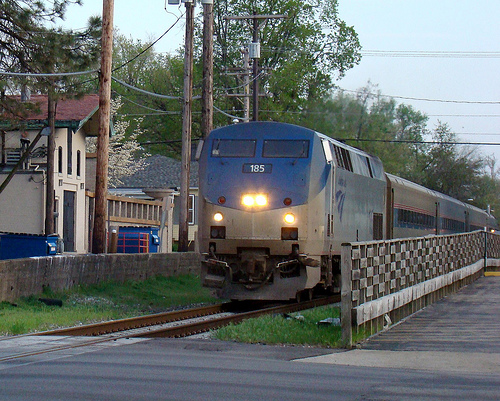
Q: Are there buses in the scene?
A: No, there are no buses.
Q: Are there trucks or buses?
A: No, there are no buses or trucks.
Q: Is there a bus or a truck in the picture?
A: No, there are no buses or trucks.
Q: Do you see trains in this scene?
A: Yes, there is a train.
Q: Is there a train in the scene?
A: Yes, there is a train.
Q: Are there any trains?
A: Yes, there is a train.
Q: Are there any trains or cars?
A: Yes, there is a train.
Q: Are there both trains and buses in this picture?
A: No, there is a train but no buses.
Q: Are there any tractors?
A: No, there are no tractors.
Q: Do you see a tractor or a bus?
A: No, there are no tractors or buses.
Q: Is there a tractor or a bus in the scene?
A: No, there are no tractors or buses.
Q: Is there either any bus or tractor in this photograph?
A: No, there are no tractors or buses.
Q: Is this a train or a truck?
A: This is a train.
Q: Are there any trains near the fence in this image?
A: Yes, there is a train near the fence.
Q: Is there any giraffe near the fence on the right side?
A: No, there is a train near the fence.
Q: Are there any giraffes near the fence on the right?
A: No, there is a train near the fence.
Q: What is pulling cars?
A: The train is pulling cars.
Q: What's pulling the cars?
A: The train is pulling cars.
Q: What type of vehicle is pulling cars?
A: The vehicle is a train.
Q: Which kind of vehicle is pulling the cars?
A: The vehicle is a train.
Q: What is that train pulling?
A: The train is pulling cars.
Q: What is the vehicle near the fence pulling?
A: The train is pulling cars.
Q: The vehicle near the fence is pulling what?
A: The train is pulling cars.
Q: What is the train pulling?
A: The train is pulling cars.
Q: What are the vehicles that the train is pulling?
A: The vehicles are cars.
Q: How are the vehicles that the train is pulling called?
A: The vehicles are cars.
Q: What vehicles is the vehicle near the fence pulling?
A: The train is pulling cars.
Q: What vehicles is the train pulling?
A: The train is pulling cars.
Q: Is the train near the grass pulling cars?
A: Yes, the train is pulling cars.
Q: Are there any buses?
A: No, there are no buses.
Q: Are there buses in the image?
A: No, there are no buses.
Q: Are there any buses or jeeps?
A: No, there are no buses or jeeps.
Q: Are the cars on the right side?
A: Yes, the cars are on the right of the image.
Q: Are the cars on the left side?
A: No, the cars are on the right of the image.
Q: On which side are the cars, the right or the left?
A: The cars are on the right of the image.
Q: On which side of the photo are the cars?
A: The cars are on the right of the image.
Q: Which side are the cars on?
A: The cars are on the right of the image.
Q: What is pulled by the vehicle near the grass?
A: The cars are pulled by the train.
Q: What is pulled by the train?
A: The cars are pulled by the train.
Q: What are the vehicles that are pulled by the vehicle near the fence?
A: The vehicles are cars.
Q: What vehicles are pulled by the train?
A: The vehicles are cars.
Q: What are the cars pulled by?
A: The cars are pulled by the train.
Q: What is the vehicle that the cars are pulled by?
A: The vehicle is a train.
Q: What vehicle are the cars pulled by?
A: The cars are pulled by the train.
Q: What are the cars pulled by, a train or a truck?
A: The cars are pulled by a train.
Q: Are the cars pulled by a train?
A: Yes, the cars are pulled by a train.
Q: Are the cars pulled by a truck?
A: No, the cars are pulled by a train.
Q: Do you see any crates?
A: No, there are no crates.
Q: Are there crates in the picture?
A: No, there are no crates.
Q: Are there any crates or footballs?
A: No, there are no crates or footballs.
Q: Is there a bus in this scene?
A: No, there are no buses.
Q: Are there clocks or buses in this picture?
A: No, there are no buses or clocks.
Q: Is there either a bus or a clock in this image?
A: No, there are no buses or clocks.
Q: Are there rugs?
A: No, there are no rugs.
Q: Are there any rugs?
A: No, there are no rugs.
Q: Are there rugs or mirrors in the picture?
A: No, there are no rugs or mirrors.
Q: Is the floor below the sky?
A: Yes, the floor is below the sky.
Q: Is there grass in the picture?
A: Yes, there is grass.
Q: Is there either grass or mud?
A: Yes, there is grass.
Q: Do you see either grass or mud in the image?
A: Yes, there is grass.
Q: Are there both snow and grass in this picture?
A: No, there is grass but no snow.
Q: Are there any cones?
A: No, there are no cones.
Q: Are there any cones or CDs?
A: No, there are no cones or cds.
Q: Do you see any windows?
A: Yes, there is a window.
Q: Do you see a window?
A: Yes, there is a window.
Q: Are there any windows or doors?
A: Yes, there is a window.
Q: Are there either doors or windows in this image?
A: Yes, there is a window.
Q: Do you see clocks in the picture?
A: No, there are no clocks.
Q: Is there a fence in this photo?
A: Yes, there is a fence.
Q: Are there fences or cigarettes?
A: Yes, there is a fence.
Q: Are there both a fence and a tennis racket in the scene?
A: No, there is a fence but no rackets.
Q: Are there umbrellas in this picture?
A: No, there are no umbrellas.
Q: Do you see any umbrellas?
A: No, there are no umbrellas.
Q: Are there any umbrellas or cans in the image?
A: No, there are no umbrellas or cans.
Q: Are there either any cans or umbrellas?
A: No, there are no umbrellas or cans.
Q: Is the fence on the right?
A: Yes, the fence is on the right of the image.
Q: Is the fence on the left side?
A: No, the fence is on the right of the image.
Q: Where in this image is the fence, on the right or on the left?
A: The fence is on the right of the image.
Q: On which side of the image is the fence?
A: The fence is on the right of the image.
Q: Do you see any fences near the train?
A: Yes, there is a fence near the train.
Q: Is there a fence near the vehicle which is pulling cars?
A: Yes, there is a fence near the train.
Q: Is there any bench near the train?
A: No, there is a fence near the train.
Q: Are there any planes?
A: No, there are no planes.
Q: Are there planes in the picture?
A: No, there are no planes.